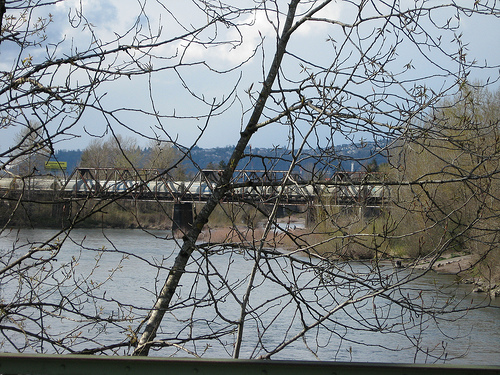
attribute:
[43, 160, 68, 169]
yellow billboard — behind the train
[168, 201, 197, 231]
bridge support — in the river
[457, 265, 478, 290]
rocks — at the edge of the river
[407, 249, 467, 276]
sandy beach — by the river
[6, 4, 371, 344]
tree branches — barren, with the train behind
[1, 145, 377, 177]
hill — in the background, with trees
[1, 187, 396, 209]
bridge — over the water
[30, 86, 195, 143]
clear sky — blue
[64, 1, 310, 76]
clouds — fluffy and white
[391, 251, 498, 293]
beach area — sandy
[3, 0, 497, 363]
tree branches — barren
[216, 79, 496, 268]
bush — overgrown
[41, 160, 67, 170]
billboard sign — yellow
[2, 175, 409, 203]
train — on a bridge, over a river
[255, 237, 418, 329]
branches — dry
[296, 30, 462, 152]
leaves — dry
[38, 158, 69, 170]
billboard — yellow